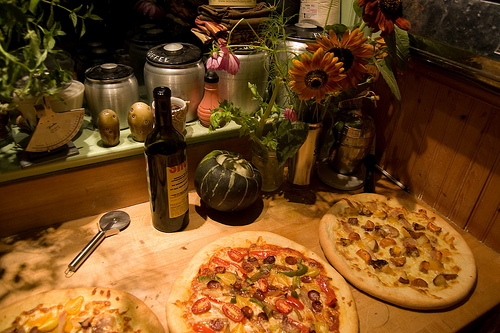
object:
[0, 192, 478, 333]
pizza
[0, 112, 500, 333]
counter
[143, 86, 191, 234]
bottle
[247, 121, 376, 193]
vase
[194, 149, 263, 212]
pumpkin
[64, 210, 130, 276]
spoon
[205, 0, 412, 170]
flower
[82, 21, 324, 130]
metal canister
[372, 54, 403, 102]
leaf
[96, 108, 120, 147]
salt shakers